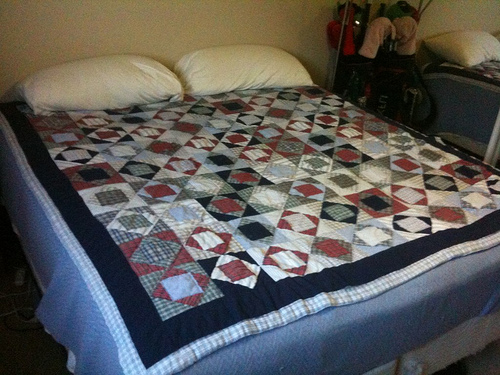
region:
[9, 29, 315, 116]
The pillows on the bed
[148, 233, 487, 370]
The mattress on the bed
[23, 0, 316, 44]
The color of the wall is white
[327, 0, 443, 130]
Personal items in the corner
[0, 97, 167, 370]
The edge of the bed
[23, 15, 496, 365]
The bedroom has a bed in it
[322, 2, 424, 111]
the golf clubs by the bed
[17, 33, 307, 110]
the pillows in the bed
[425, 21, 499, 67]
the pillow reflection in the mirror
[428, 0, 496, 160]
the mirror by the bed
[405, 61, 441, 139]
the strap of the golf bag in the mirror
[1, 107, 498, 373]
the blankets on the bed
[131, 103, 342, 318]
the square and diamond design on the bedspread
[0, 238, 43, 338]
the cords on the floor under the bed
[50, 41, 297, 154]
white pillows on bed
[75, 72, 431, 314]
red and black blanket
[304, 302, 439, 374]
blue blanket on bed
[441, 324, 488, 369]
white springs under bed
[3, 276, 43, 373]
carpet is dark grey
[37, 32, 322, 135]
two white and fluffy pillows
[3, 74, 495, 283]
bed is made with blanket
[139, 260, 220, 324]
multi color quilt square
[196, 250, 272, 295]
multi color quilt square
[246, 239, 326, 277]
multi color quilt square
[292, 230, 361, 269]
multi color quilt square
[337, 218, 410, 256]
multi color quilt square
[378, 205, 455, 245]
multi color quilt square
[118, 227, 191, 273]
multi color quilt square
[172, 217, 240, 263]
multi color quilt square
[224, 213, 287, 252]
multi color quilt square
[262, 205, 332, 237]
multi color quilt square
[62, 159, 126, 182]
multi color square of quilt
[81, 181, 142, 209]
multi color square of quilt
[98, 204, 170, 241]
multi color square of quilt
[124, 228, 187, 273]
multi color square of quilt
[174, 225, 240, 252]
multi color square of quilt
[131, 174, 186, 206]
multi color square of quilt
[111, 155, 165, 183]
multi color square of quilt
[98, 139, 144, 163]
multi color square of quilt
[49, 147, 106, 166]
multi color square of quilt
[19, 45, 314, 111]
two white pillows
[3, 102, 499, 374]
blue bordered patterned quilt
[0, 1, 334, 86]
white wall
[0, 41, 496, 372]
large bed with two pillows on it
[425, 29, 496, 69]
white pillow reflection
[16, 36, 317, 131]
a pair of pillows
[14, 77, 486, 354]
a multicolored bed spread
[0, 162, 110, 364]
light blue trim on cover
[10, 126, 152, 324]
dark blue trim on cover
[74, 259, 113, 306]
plaid trim on cover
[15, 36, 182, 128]
the pillow is white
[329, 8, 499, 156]
reflection in the mirror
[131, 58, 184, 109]
wrinkle on the pillow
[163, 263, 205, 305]
a blue quilt square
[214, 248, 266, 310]
a red quilt square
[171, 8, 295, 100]
a pillow on the bed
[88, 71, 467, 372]
a quilt on the bed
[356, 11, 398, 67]
golf clubs that are covered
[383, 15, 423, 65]
golf clubs that are covered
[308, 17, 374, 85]
golf clubs that are covered